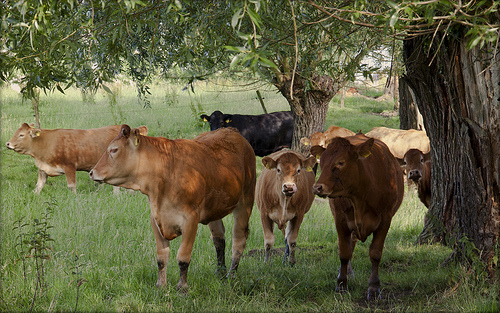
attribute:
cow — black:
[318, 126, 408, 298]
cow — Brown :
[401, 148, 434, 215]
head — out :
[399, 148, 434, 188]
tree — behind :
[387, 10, 497, 275]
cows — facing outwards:
[88, 123, 258, 294]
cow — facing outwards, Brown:
[87, 121, 260, 294]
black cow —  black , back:
[204, 106, 294, 144]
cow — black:
[94, 97, 259, 298]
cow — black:
[198, 100, 302, 156]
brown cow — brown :
[311, 130, 408, 295]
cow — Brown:
[255, 146, 313, 269]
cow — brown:
[2, 122, 167, 222]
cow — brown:
[88, 123, 301, 283]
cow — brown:
[179, 88, 331, 148]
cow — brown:
[240, 133, 335, 228]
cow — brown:
[283, 119, 454, 251]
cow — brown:
[398, 141, 458, 222]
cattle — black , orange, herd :
[3, 81, 448, 301]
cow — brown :
[395, 147, 434, 212]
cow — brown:
[244, 144, 333, 267]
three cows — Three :
[312, 134, 405, 303]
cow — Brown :
[396, 146, 436, 210]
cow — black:
[196, 102, 320, 166]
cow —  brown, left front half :
[3, 118, 123, 202]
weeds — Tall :
[1, 196, 58, 311]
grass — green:
[2, 86, 487, 303]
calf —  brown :
[396, 143, 445, 200]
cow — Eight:
[307, 129, 414, 277]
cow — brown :
[310, 128, 405, 298]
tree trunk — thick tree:
[412, 40, 499, 270]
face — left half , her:
[84, 125, 268, 287]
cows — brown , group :
[11, 87, 433, 305]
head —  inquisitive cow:
[290, 123, 382, 197]